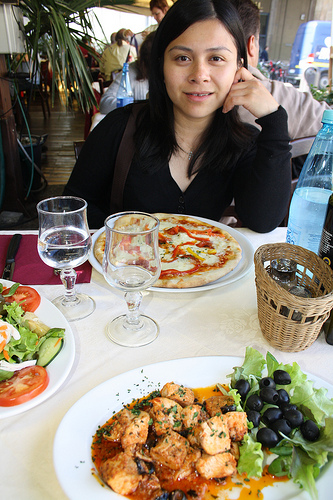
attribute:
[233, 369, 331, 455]
olives — black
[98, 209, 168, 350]
wine glass — clear, shiny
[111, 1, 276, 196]
hair — black 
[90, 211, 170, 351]
glass — empty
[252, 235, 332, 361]
basket — brown, wicker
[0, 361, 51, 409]
tomato — red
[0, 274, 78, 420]
plate — white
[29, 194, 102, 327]
glass — clear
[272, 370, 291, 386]
olive — black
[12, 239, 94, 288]
napkin — maroon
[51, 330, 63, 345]
carrot — orange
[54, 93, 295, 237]
black shirt —  black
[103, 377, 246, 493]
chicken — delicious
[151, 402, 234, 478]
chicken — seasoned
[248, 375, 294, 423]
olives — black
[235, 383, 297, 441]
olives —  black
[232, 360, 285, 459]
lettuce — green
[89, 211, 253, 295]
plate — white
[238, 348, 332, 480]
herb — green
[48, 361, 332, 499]
plate — white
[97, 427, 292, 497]
sauce — red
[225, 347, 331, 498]
herbs — green